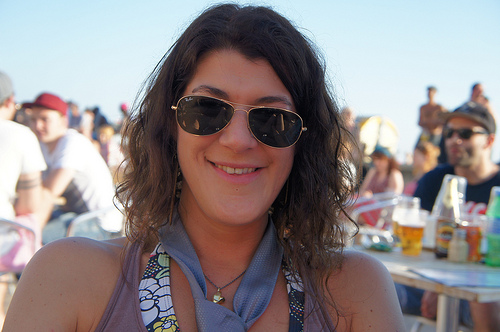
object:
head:
[121, 5, 336, 219]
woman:
[0, 2, 405, 332]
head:
[446, 106, 496, 166]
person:
[412, 104, 499, 213]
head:
[31, 94, 67, 142]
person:
[21, 94, 125, 244]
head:
[0, 71, 17, 121]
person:
[0, 72, 47, 271]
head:
[429, 87, 437, 97]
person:
[419, 87, 443, 126]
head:
[372, 150, 389, 170]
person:
[359, 147, 404, 225]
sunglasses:
[171, 95, 304, 149]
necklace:
[202, 272, 245, 304]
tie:
[158, 221, 285, 331]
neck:
[179, 183, 270, 249]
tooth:
[226, 167, 234, 173]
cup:
[398, 210, 424, 255]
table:
[350, 248, 500, 331]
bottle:
[487, 187, 500, 265]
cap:
[23, 94, 68, 115]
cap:
[433, 103, 496, 134]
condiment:
[447, 229, 469, 261]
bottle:
[435, 178, 459, 256]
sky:
[0, 0, 499, 120]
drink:
[466, 226, 481, 261]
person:
[471, 84, 489, 111]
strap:
[93, 233, 141, 329]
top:
[306, 257, 333, 331]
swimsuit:
[141, 242, 179, 331]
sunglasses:
[444, 128, 472, 139]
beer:
[400, 226, 422, 255]